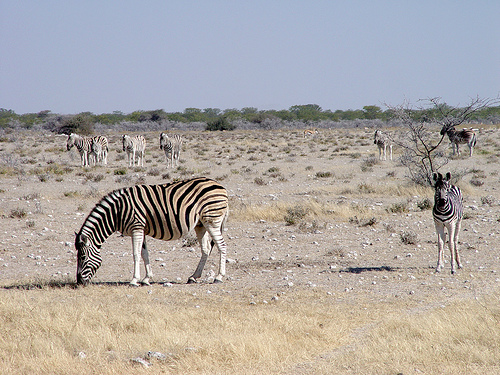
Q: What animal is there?
A: Zebras.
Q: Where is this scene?
A: The bush.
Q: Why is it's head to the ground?
A: Grazing.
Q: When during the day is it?
A: Daytime.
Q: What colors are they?
A: Black-and-white.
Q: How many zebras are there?
A: 7.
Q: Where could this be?
A: Africa.